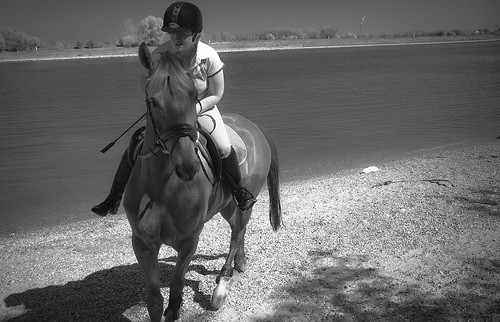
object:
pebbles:
[314, 182, 327, 191]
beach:
[0, 142, 499, 320]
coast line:
[0, 32, 500, 67]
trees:
[127, 11, 175, 55]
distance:
[0, 15, 499, 53]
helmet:
[150, 1, 211, 50]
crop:
[82, 108, 157, 154]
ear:
[187, 29, 216, 48]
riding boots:
[76, 125, 148, 224]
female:
[86, 0, 266, 216]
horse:
[85, 36, 291, 322]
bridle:
[145, 112, 210, 166]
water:
[0, 42, 500, 228]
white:
[211, 276, 238, 297]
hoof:
[201, 284, 245, 316]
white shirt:
[157, 37, 234, 116]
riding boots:
[213, 142, 268, 215]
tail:
[257, 133, 292, 234]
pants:
[188, 102, 240, 163]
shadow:
[0, 240, 239, 322]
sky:
[0, 0, 500, 36]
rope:
[120, 122, 154, 166]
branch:
[369, 174, 455, 192]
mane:
[122, 34, 204, 103]